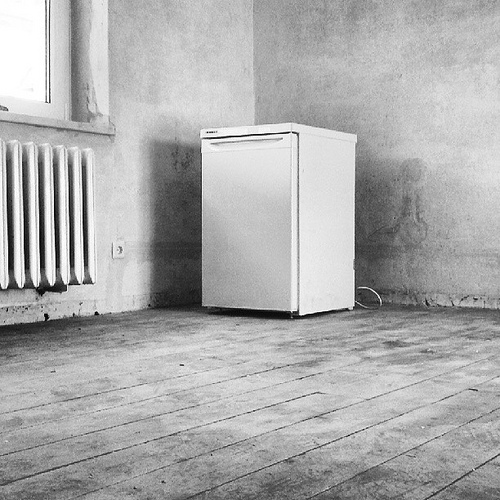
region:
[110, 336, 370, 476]
hard wood piece on floor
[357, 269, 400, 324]
white wire handing from fridge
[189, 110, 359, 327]
white small fridge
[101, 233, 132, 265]
white telephone cord outlet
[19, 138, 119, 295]
heated radiator off ground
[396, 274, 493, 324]
chipped paint on baseboard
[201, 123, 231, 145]
brand name of fridge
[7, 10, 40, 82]
glass window pane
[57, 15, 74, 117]
white wooden frame paint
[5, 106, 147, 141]
empty white window sill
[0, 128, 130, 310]
White radiator on the left side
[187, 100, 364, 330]
White small fridge in the back of the room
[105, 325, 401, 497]
Dirty wooden floorboards slanting diagonally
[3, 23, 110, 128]
Bright window in the upper left corner of the room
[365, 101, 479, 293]
Stained spot on the wall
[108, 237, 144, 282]
Plug for an electrical device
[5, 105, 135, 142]
Large white windowsill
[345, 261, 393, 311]
White cord connecting the fridge to the wall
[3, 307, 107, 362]
Dirt below the radiator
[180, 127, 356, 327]
Large white electrical appliance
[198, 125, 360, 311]
a mini fridge sitting in the corner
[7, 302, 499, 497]
the wooden floor of the room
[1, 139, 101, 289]
a radiator attached to the wall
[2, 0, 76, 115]
a window above the radiator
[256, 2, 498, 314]
the wall behind the mini fridge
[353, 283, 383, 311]
the plug for the mini fridge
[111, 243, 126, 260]
a plug in the wall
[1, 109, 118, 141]
the sill below the window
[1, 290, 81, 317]
the wall below the radiator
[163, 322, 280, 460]
more of the floor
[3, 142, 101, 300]
radiator on the wall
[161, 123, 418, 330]
small white refrigerator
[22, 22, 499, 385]
picture is in black and white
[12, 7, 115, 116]
light coming in from the window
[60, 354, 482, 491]
floor made of wood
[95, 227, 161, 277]
electrical plug in the wall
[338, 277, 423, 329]
cord of the refrigerator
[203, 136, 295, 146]
handle of the refrigerator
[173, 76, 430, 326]
the refrigerator in the corner of the room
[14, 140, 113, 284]
the radiator is white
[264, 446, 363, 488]
dirt on wood floor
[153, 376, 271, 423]
lines on the floor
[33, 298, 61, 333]
black spots on the wall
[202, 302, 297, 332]
shadow under the appliance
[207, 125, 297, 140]
edge of the white appliance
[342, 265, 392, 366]
large electrical cord on ground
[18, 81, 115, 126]
large white window sill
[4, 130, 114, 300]
white radiator on the wall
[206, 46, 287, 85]
edge of the walls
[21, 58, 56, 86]
clear panes of glass